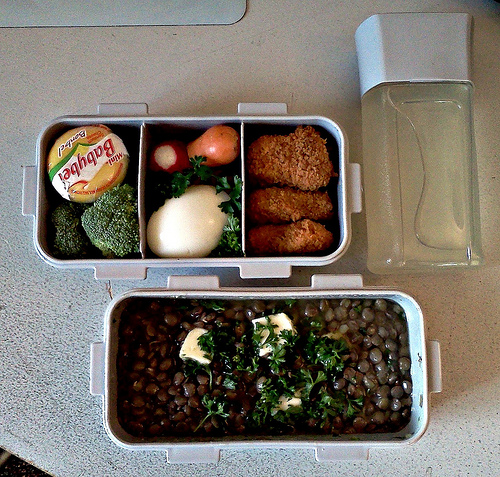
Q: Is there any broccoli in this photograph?
A: Yes, there is broccoli.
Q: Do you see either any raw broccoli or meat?
A: Yes, there is raw broccoli.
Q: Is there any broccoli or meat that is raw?
A: Yes, the broccoli is raw.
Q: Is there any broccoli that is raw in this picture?
A: Yes, there is raw broccoli.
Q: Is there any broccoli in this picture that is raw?
A: Yes, there is broccoli that is raw.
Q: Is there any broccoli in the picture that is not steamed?
A: Yes, there is raw broccoli.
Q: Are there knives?
A: No, there are no knives.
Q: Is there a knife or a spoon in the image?
A: No, there are no knives or spoons.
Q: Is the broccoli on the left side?
A: Yes, the broccoli is on the left of the image.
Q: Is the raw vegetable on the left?
A: Yes, the broccoli is on the left of the image.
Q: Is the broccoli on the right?
A: No, the broccoli is on the left of the image.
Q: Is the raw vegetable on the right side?
A: No, the broccoli is on the left of the image.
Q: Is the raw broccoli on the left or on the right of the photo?
A: The broccoli is on the left of the image.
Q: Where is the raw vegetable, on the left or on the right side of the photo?
A: The broccoli is on the left of the image.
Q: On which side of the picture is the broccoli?
A: The broccoli is on the left of the image.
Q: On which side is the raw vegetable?
A: The broccoli is on the left of the image.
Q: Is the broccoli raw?
A: Yes, the broccoli is raw.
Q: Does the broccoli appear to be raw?
A: Yes, the broccoli is raw.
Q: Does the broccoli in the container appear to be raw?
A: Yes, the broccoli is raw.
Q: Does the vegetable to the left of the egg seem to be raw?
A: Yes, the broccoli is raw.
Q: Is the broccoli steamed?
A: No, the broccoli is raw.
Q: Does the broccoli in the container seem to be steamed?
A: No, the broccoli is raw.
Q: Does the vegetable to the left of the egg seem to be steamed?
A: No, the broccoli is raw.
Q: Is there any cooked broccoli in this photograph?
A: No, there is broccoli but it is raw.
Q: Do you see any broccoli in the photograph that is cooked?
A: No, there is broccoli but it is raw.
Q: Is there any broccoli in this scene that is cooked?
A: No, there is broccoli but it is raw.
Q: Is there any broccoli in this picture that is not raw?
A: No, there is broccoli but it is raw.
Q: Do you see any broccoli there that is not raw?
A: No, there is broccoli but it is raw.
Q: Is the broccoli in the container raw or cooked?
A: The broccoli is raw.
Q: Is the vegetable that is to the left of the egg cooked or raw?
A: The broccoli is raw.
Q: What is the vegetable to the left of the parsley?
A: The vegetable is broccoli.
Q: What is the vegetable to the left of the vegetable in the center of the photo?
A: The vegetable is broccoli.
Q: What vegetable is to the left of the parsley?
A: The vegetable is broccoli.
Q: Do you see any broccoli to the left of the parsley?
A: Yes, there is broccoli to the left of the parsley.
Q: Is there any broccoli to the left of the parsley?
A: Yes, there is broccoli to the left of the parsley.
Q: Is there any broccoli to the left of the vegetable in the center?
A: Yes, there is broccoli to the left of the parsley.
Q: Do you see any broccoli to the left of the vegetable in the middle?
A: Yes, there is broccoli to the left of the parsley.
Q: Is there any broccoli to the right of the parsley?
A: No, the broccoli is to the left of the parsley.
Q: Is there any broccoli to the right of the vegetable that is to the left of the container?
A: No, the broccoli is to the left of the parsley.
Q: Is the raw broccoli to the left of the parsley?
A: Yes, the broccoli is to the left of the parsley.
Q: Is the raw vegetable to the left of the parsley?
A: Yes, the broccoli is to the left of the parsley.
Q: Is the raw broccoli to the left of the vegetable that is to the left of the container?
A: Yes, the broccoli is to the left of the parsley.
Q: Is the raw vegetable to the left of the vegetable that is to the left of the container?
A: Yes, the broccoli is to the left of the parsley.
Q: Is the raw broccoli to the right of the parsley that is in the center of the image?
A: No, the broccoli is to the left of the parsley.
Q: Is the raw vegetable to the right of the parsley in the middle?
A: No, the broccoli is to the left of the parsley.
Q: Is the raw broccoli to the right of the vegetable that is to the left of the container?
A: No, the broccoli is to the left of the parsley.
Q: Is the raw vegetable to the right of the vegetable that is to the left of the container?
A: No, the broccoli is to the left of the parsley.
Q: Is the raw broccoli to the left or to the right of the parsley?
A: The broccoli is to the left of the parsley.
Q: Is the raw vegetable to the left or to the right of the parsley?
A: The broccoli is to the left of the parsley.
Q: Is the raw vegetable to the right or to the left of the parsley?
A: The broccoli is to the left of the parsley.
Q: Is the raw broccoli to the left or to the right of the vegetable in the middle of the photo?
A: The broccoli is to the left of the parsley.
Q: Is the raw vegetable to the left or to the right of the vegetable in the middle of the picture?
A: The broccoli is to the left of the parsley.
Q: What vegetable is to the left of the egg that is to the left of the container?
A: The vegetable is broccoli.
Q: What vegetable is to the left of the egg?
A: The vegetable is broccoli.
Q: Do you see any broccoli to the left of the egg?
A: Yes, there is broccoli to the left of the egg.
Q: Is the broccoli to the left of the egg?
A: Yes, the broccoli is to the left of the egg.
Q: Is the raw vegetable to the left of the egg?
A: Yes, the broccoli is to the left of the egg.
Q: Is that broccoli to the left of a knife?
A: No, the broccoli is to the left of the egg.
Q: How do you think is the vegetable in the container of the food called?
A: The vegetable is broccoli.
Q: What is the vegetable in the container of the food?
A: The vegetable is broccoli.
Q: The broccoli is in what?
A: The broccoli is in the container.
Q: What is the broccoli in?
A: The broccoli is in the container.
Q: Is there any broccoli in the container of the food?
A: Yes, there is broccoli in the container.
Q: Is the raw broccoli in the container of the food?
A: Yes, the broccoli is in the container.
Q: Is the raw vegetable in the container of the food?
A: Yes, the broccoli is in the container.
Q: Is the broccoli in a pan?
A: No, the broccoli is in the container.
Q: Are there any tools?
A: No, there are no tools.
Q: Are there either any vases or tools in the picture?
A: No, there are no tools or vases.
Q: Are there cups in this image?
A: No, there are no cups.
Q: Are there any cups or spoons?
A: No, there are no cups or spoons.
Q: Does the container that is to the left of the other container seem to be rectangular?
A: Yes, the container is rectangular.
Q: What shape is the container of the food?
A: The container is rectangular.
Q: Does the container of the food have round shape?
A: No, the container is rectangular.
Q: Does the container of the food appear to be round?
A: No, the container is rectangular.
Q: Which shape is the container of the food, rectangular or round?
A: The container is rectangular.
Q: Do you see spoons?
A: No, there are no spoons.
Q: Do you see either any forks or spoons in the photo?
A: No, there are no spoons or forks.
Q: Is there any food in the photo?
A: Yes, there is food.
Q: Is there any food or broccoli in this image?
A: Yes, there is food.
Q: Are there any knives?
A: No, there are no knives.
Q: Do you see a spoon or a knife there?
A: No, there are no knives or spoons.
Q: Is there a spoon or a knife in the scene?
A: No, there are no knives or spoons.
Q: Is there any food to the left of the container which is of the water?
A: Yes, there is food to the left of the container.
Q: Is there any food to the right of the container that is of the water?
A: No, the food is to the left of the container.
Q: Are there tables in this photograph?
A: Yes, there is a table.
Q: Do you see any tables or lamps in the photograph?
A: Yes, there is a table.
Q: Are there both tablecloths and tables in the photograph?
A: No, there is a table but no tablecloths.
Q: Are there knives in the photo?
A: No, there are no knives.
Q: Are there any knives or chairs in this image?
A: No, there are no knives or chairs.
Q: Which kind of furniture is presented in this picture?
A: The furniture is a table.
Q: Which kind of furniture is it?
A: The piece of furniture is a table.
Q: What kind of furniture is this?
A: This is a table.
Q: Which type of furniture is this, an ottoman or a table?
A: This is a table.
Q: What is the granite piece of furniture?
A: The piece of furniture is a table.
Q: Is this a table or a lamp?
A: This is a table.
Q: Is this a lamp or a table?
A: This is a table.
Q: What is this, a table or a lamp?
A: This is a table.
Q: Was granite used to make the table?
A: Yes, the table is made of granite.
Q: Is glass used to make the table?
A: No, the table is made of granite.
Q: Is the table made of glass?
A: No, the table is made of granite.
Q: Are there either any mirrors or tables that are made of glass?
A: No, there is a table but it is made of granite.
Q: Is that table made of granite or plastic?
A: The table is made of granite.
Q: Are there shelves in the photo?
A: No, there are no shelves.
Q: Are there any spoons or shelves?
A: No, there are no shelves or spoons.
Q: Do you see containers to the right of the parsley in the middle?
A: Yes, there is a container to the right of the parsley.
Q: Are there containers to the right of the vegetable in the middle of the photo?
A: Yes, there is a container to the right of the parsley.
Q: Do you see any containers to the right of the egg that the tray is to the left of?
A: Yes, there is a container to the right of the egg.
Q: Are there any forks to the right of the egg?
A: No, there is a container to the right of the egg.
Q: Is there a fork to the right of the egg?
A: No, there is a container to the right of the egg.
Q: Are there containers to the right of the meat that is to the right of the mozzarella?
A: Yes, there is a container to the right of the meat.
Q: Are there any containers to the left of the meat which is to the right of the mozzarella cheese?
A: No, the container is to the right of the meat.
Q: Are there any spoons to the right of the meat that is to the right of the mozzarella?
A: No, there is a container to the right of the meat.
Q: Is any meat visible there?
A: Yes, there is meat.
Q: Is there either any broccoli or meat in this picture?
A: Yes, there is meat.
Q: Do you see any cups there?
A: No, there are no cups.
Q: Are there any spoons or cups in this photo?
A: No, there are no cups or spoons.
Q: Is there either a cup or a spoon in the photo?
A: No, there are no cups or spoons.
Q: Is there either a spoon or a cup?
A: No, there are no cups or spoons.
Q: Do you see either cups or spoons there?
A: No, there are no cups or spoons.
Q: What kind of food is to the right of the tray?
A: The food is meat.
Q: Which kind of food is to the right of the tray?
A: The food is meat.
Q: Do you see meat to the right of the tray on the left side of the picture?
A: Yes, there is meat to the right of the tray.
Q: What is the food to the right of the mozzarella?
A: The food is meat.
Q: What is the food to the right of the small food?
A: The food is meat.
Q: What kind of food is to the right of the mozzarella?
A: The food is meat.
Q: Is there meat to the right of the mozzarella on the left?
A: Yes, there is meat to the right of the mozzarella cheese.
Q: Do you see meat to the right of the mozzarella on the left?
A: Yes, there is meat to the right of the mozzarella cheese.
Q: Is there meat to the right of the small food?
A: Yes, there is meat to the right of the mozzarella cheese.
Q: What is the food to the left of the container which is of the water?
A: The food is meat.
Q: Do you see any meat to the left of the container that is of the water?
A: Yes, there is meat to the left of the container.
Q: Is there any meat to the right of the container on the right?
A: No, the meat is to the left of the container.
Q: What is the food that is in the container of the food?
A: The food is meat.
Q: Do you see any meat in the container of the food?
A: Yes, there is meat in the container.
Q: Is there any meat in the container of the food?
A: Yes, there is meat in the container.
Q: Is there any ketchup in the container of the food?
A: No, there is meat in the container.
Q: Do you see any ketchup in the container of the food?
A: No, there is meat in the container.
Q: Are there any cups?
A: No, there are no cups.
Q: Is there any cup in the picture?
A: No, there are no cups.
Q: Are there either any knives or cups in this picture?
A: No, there are no cups or knives.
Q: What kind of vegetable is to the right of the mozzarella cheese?
A: The vegetable is parsley.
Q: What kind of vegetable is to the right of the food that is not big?
A: The vegetable is parsley.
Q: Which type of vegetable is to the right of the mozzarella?
A: The vegetable is parsley.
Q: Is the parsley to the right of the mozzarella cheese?
A: Yes, the parsley is to the right of the mozzarella cheese.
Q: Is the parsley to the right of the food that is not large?
A: Yes, the parsley is to the right of the mozzarella cheese.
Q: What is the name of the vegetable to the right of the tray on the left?
A: The vegetable is parsley.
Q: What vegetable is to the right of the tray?
A: The vegetable is parsley.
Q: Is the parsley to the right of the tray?
A: Yes, the parsley is to the right of the tray.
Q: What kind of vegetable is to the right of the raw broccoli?
A: The vegetable is parsley.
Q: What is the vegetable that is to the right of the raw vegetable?
A: The vegetable is parsley.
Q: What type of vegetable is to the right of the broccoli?
A: The vegetable is parsley.